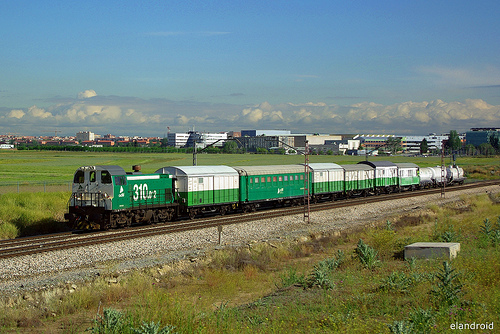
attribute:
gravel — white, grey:
[4, 229, 201, 289]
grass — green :
[199, 256, 408, 332]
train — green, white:
[178, 136, 456, 211]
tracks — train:
[3, 169, 498, 282]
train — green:
[63, 162, 467, 230]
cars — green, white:
[179, 157, 428, 221]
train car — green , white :
[153, 164, 239, 221]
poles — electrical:
[302, 138, 312, 222]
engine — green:
[66, 163, 179, 231]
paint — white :
[319, 171, 326, 173]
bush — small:
[355, 237, 387, 272]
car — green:
[62, 163, 173, 231]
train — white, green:
[26, 152, 308, 224]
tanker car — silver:
[447, 163, 465, 186]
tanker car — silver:
[417, 165, 444, 183]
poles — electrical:
[437, 141, 449, 204]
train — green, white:
[67, 159, 419, 216]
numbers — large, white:
[128, 183, 156, 200]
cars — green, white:
[167, 153, 467, 211]